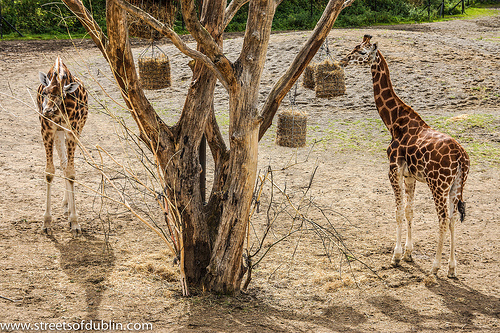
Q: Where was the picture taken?
A: It was taken at the pasture.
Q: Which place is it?
A: It is a pasture.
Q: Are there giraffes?
A: Yes, there is a giraffe.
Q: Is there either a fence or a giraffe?
A: Yes, there is a giraffe.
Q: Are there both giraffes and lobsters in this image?
A: No, there is a giraffe but no lobsters.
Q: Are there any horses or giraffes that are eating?
A: Yes, the giraffe is eating.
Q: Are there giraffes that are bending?
A: Yes, there is a giraffe that is bending.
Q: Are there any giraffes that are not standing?
A: Yes, there is a giraffe that is bending.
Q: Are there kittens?
A: No, there are no kittens.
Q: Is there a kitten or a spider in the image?
A: No, there are no kittens or spiders.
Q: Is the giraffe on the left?
A: Yes, the giraffe is on the left of the image.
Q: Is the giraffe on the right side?
A: No, the giraffe is on the left of the image.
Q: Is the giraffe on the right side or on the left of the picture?
A: The giraffe is on the left of the image.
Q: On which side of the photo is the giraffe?
A: The giraffe is on the left of the image.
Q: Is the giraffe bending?
A: Yes, the giraffe is bending.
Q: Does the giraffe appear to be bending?
A: Yes, the giraffe is bending.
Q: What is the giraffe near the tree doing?
A: The giraffe is bending.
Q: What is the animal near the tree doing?
A: The giraffe is bending.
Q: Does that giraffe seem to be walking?
A: No, the giraffe is bending.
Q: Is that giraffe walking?
A: No, the giraffe is bending.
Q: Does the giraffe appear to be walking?
A: No, the giraffe is bending.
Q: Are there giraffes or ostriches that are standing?
A: No, there is a giraffe but it is bending.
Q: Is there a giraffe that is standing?
A: No, there is a giraffe but it is bending.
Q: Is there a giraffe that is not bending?
A: No, there is a giraffe but it is bending.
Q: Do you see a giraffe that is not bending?
A: No, there is a giraffe but it is bending.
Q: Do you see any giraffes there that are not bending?
A: No, there is a giraffe but it is bending.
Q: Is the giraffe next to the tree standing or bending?
A: The giraffe is bending.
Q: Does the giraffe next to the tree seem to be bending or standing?
A: The giraffe is bending.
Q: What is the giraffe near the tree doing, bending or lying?
A: The giraffe is bending.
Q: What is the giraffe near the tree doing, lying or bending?
A: The giraffe is bending.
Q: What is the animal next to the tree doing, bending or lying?
A: The giraffe is bending.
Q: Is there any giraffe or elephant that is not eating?
A: No, there is a giraffe but it is eating.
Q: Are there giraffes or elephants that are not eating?
A: No, there is a giraffe but it is eating.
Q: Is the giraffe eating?
A: Yes, the giraffe is eating.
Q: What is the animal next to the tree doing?
A: The giraffe is eating.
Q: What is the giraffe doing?
A: The giraffe is eating.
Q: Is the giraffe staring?
A: No, the giraffe is eating.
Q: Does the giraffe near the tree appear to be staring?
A: No, the giraffe is eating.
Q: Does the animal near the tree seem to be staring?
A: No, the giraffe is eating.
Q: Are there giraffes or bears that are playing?
A: No, there is a giraffe but it is eating.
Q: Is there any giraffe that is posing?
A: No, there is a giraffe but it is eating.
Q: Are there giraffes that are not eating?
A: No, there is a giraffe but it is eating.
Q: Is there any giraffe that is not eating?
A: No, there is a giraffe but it is eating.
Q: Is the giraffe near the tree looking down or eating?
A: The giraffe is eating.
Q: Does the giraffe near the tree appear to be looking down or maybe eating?
A: The giraffe is eating.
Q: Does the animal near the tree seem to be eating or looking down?
A: The giraffe is eating.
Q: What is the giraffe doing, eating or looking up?
A: The giraffe is eating.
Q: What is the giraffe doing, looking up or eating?
A: The giraffe is eating.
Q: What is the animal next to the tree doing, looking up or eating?
A: The giraffe is eating.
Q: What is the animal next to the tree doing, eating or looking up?
A: The giraffe is eating.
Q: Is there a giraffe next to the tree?
A: Yes, there is a giraffe next to the tree.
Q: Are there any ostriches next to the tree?
A: No, there is a giraffe next to the tree.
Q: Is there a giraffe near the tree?
A: Yes, there is a giraffe near the tree.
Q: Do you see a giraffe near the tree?
A: Yes, there is a giraffe near the tree.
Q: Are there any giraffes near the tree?
A: Yes, there is a giraffe near the tree.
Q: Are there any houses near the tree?
A: No, there is a giraffe near the tree.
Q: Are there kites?
A: No, there are no kites.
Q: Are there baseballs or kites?
A: No, there are no kites or baseballs.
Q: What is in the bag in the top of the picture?
A: The hay is in the bag.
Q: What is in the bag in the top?
A: The hay is in the bag.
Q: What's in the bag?
A: The hay is in the bag.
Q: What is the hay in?
A: The hay is in the bag.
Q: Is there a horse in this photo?
A: No, there are no horses.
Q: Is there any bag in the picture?
A: Yes, there is a bag.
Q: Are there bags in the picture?
A: Yes, there is a bag.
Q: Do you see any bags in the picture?
A: Yes, there is a bag.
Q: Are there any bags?
A: Yes, there is a bag.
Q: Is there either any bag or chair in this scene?
A: Yes, there is a bag.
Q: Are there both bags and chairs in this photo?
A: No, there is a bag but no chairs.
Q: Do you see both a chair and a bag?
A: No, there is a bag but no chairs.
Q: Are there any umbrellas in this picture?
A: No, there are no umbrellas.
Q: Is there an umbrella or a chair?
A: No, there are no umbrellas or chairs.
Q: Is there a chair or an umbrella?
A: No, there are no umbrellas or chairs.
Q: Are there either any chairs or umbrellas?
A: No, there are no umbrellas or chairs.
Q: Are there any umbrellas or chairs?
A: No, there are no umbrellas or chairs.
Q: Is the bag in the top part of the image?
A: Yes, the bag is in the top of the image.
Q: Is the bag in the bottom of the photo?
A: No, the bag is in the top of the image.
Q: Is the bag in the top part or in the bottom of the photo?
A: The bag is in the top of the image.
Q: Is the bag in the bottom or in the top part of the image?
A: The bag is in the top of the image.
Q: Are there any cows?
A: No, there are no cows.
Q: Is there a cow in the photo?
A: No, there are no cows.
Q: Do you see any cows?
A: No, there are no cows.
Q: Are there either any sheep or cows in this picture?
A: No, there are no cows or sheep.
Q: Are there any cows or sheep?
A: No, there are no cows or sheep.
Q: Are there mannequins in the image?
A: No, there are no mannequins.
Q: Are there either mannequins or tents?
A: No, there are no mannequins or tents.